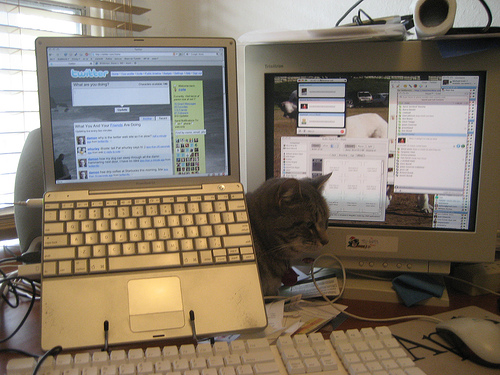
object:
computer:
[225, 33, 499, 309]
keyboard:
[42, 192, 256, 280]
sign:
[344, 235, 399, 253]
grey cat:
[231, 171, 337, 303]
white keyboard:
[0, 326, 427, 373]